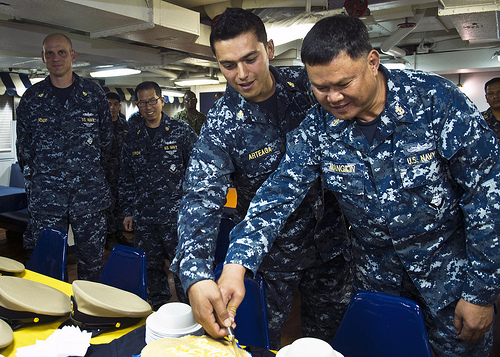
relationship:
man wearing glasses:
[127, 81, 194, 229] [135, 94, 163, 107]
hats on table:
[58, 261, 131, 339] [113, 335, 141, 356]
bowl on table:
[149, 298, 200, 335] [113, 335, 141, 356]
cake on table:
[178, 331, 223, 357] [113, 335, 141, 356]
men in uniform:
[200, 7, 448, 288] [338, 139, 448, 281]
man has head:
[127, 81, 194, 229] [126, 84, 164, 122]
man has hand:
[127, 81, 194, 229] [112, 205, 140, 234]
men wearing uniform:
[200, 7, 448, 288] [338, 139, 448, 281]